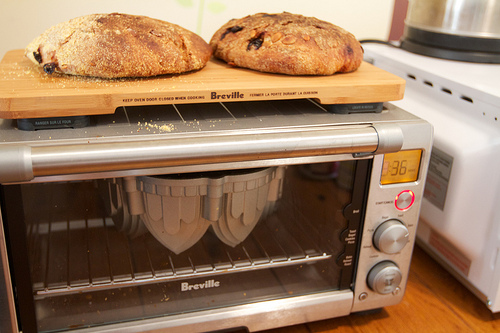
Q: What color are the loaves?
A: Brown.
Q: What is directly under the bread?
A: A board.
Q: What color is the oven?
A: Gray.